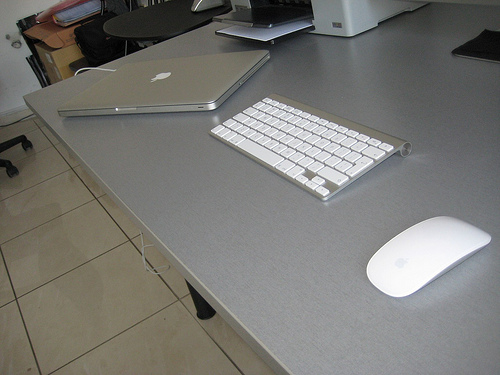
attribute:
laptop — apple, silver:
[53, 47, 272, 111]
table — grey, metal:
[28, 14, 496, 374]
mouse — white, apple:
[365, 207, 495, 308]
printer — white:
[193, 2, 453, 51]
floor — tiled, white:
[0, 109, 293, 373]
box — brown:
[27, 41, 100, 77]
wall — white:
[7, 2, 51, 123]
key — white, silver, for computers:
[205, 93, 413, 200]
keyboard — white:
[257, 132, 270, 146]